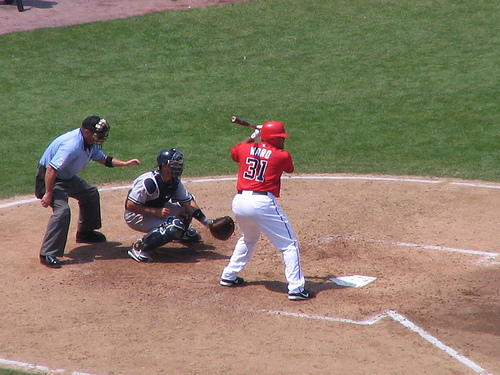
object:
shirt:
[231, 141, 294, 198]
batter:
[219, 121, 312, 300]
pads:
[125, 170, 179, 209]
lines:
[252, 308, 490, 375]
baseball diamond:
[0, 170, 500, 375]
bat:
[231, 116, 261, 130]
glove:
[250, 124, 263, 140]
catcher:
[124, 147, 234, 262]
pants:
[35, 175, 101, 257]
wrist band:
[105, 156, 113, 168]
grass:
[0, 0, 499, 199]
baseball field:
[0, 0, 500, 375]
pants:
[221, 190, 306, 294]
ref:
[35, 115, 140, 268]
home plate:
[329, 274, 377, 288]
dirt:
[1, 172, 500, 375]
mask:
[82, 118, 110, 145]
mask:
[169, 151, 184, 186]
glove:
[210, 216, 235, 241]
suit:
[34, 127, 106, 257]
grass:
[1, 60, 473, 182]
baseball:
[355, 223, 410, 258]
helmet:
[260, 121, 290, 141]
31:
[243, 157, 267, 183]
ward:
[249, 146, 272, 159]